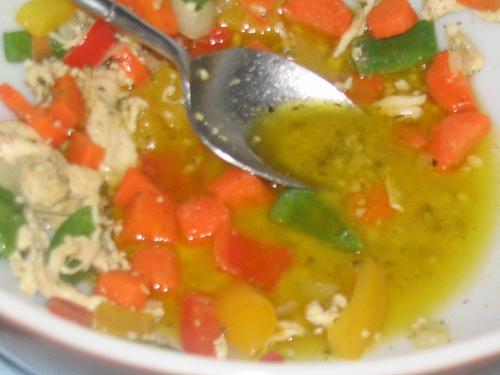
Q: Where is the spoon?
A: In the bowl.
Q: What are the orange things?
A: Carrots.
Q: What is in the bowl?
A: Soup.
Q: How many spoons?
A: One.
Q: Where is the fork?
A: There isn't one.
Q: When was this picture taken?
A: At meal time.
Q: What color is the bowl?
A: White.